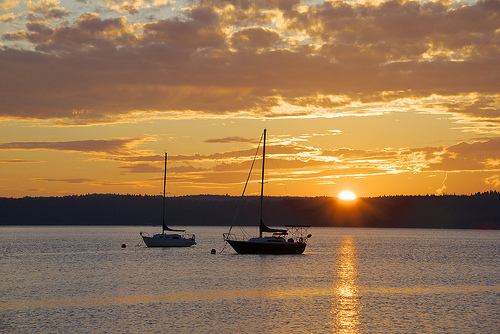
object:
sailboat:
[224, 127, 311, 253]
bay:
[1, 200, 499, 333]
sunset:
[1, 1, 499, 198]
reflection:
[330, 231, 376, 333]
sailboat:
[139, 152, 197, 248]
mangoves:
[313, 194, 500, 228]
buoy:
[209, 245, 220, 256]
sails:
[260, 222, 290, 235]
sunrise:
[0, 2, 499, 333]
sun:
[338, 187, 358, 204]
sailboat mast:
[256, 128, 269, 240]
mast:
[161, 152, 171, 234]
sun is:
[329, 188, 366, 332]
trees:
[2, 194, 142, 228]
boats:
[139, 128, 313, 255]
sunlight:
[320, 202, 363, 228]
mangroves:
[277, 190, 499, 228]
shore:
[0, 223, 500, 332]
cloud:
[1, 27, 500, 125]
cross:
[333, 230, 358, 333]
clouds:
[314, 140, 399, 187]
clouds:
[202, 78, 385, 120]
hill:
[0, 192, 499, 227]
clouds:
[141, 30, 394, 82]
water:
[0, 224, 500, 331]